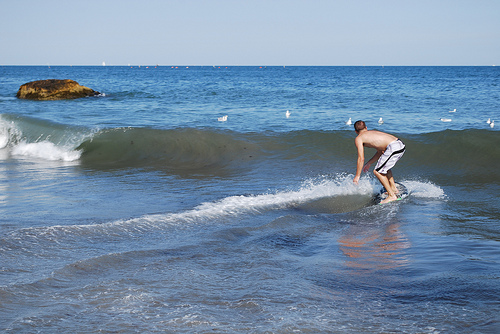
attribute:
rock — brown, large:
[4, 67, 92, 102]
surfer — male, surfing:
[342, 117, 409, 200]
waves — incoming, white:
[134, 114, 194, 153]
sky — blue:
[95, 18, 133, 42]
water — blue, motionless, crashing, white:
[254, 227, 279, 260]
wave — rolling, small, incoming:
[107, 122, 131, 145]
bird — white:
[209, 110, 230, 123]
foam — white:
[30, 137, 50, 163]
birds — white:
[272, 106, 294, 120]